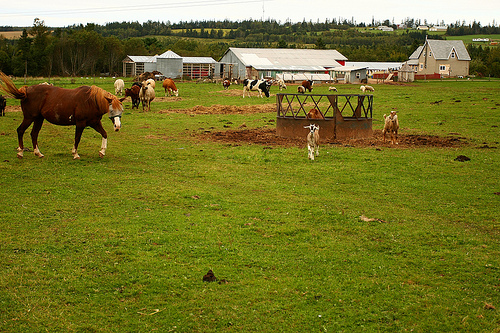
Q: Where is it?
A: This is at the field.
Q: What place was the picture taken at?
A: It was taken at the field.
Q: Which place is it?
A: It is a field.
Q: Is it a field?
A: Yes, it is a field.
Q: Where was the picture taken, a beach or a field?
A: It was taken at a field.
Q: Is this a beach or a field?
A: It is a field.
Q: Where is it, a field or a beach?
A: It is a field.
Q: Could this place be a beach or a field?
A: It is a field.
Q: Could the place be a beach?
A: No, it is a field.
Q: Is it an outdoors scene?
A: Yes, it is outdoors.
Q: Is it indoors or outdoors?
A: It is outdoors.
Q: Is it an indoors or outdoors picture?
A: It is outdoors.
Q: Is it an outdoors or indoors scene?
A: It is outdoors.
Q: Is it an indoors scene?
A: No, it is outdoors.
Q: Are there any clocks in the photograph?
A: No, there are no clocks.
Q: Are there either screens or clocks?
A: No, there are no clocks or screens.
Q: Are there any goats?
A: Yes, there is a goat.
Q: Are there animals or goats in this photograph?
A: Yes, there is a goat.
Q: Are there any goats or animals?
A: Yes, there is a goat.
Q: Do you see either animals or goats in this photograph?
A: Yes, there is a goat.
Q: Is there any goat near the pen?
A: Yes, there is a goat near the pen.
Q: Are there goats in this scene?
A: Yes, there is a goat.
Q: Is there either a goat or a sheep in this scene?
A: Yes, there is a goat.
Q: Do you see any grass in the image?
A: Yes, there is grass.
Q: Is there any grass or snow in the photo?
A: Yes, there is grass.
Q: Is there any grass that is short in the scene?
A: Yes, there is short grass.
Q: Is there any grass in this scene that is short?
A: Yes, there is grass that is short.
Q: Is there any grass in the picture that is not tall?
A: Yes, there is short grass.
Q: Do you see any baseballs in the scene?
A: No, there are no baseballs.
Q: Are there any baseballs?
A: No, there are no baseballs.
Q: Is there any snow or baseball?
A: No, there are no baseballs or snow.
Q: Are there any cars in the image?
A: No, there are no cars.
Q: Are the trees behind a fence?
A: No, the trees are behind a barn.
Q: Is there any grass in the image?
A: Yes, there is grass.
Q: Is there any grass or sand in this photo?
A: Yes, there is grass.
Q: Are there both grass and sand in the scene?
A: No, there is grass but no sand.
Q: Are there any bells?
A: No, there are no bells.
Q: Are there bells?
A: No, there are no bells.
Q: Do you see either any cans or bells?
A: No, there are no bells or cans.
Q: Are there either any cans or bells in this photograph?
A: No, there are no bells or cans.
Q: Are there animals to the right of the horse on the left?
A: Yes, there is an animal to the right of the horse.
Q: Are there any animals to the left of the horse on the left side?
A: No, the animal is to the right of the horse.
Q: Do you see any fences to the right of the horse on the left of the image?
A: No, there is an animal to the right of the horse.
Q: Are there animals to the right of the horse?
A: Yes, there is an animal to the right of the horse.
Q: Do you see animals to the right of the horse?
A: Yes, there is an animal to the right of the horse.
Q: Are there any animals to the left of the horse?
A: No, the animal is to the right of the horse.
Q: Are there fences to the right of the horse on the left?
A: No, there is an animal to the right of the horse.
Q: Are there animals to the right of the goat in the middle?
A: Yes, there is an animal to the right of the goat.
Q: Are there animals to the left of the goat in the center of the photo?
A: No, the animal is to the right of the goat.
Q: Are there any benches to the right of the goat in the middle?
A: No, there is an animal to the right of the goat.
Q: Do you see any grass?
A: Yes, there is grass.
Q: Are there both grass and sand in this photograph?
A: No, there is grass but no sand.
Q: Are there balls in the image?
A: No, there are no balls.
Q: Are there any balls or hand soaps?
A: No, there are no balls or hand soaps.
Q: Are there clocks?
A: No, there are no clocks.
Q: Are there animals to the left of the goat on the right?
A: Yes, there is an animal to the left of the goat.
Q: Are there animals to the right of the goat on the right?
A: No, the animal is to the left of the goat.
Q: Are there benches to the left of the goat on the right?
A: No, there is an animal to the left of the goat.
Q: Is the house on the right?
A: Yes, the house is on the right of the image.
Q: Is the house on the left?
A: No, the house is on the right of the image.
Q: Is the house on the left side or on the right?
A: The house is on the right of the image.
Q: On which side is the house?
A: The house is on the right of the image.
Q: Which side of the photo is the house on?
A: The house is on the right of the image.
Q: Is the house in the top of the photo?
A: Yes, the house is in the top of the image.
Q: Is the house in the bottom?
A: No, the house is in the top of the image.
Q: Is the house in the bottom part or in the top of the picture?
A: The house is in the top of the image.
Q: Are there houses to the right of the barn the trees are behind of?
A: Yes, there is a house to the right of the barn.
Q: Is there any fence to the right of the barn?
A: No, there is a house to the right of the barn.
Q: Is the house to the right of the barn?
A: Yes, the house is to the right of the barn.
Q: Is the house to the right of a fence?
A: No, the house is to the right of the barn.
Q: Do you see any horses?
A: Yes, there is a horse.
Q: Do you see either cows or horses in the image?
A: Yes, there is a horse.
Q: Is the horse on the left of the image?
A: Yes, the horse is on the left of the image.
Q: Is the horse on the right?
A: No, the horse is on the left of the image.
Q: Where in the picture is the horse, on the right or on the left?
A: The horse is on the left of the image.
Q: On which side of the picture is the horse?
A: The horse is on the left of the image.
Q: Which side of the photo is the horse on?
A: The horse is on the left of the image.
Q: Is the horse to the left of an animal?
A: Yes, the horse is to the left of an animal.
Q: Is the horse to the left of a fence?
A: No, the horse is to the left of an animal.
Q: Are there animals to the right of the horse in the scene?
A: Yes, there is an animal to the right of the horse.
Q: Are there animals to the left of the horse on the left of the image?
A: No, the animal is to the right of the horse.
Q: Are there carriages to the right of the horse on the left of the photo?
A: No, there is an animal to the right of the horse.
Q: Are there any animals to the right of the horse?
A: Yes, there is an animal to the right of the horse.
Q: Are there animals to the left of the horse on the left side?
A: No, the animal is to the right of the horse.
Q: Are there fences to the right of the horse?
A: No, there is an animal to the right of the horse.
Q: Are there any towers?
A: No, there are no towers.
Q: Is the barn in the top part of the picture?
A: Yes, the barn is in the top of the image.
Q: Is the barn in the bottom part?
A: No, the barn is in the top of the image.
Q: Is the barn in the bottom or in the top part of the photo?
A: The barn is in the top of the image.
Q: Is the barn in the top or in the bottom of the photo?
A: The barn is in the top of the image.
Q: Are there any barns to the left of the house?
A: Yes, there is a barn to the left of the house.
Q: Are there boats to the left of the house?
A: No, there is a barn to the left of the house.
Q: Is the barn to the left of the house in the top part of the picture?
A: Yes, the barn is to the left of the house.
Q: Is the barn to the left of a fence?
A: No, the barn is to the left of the house.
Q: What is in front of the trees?
A: The barn is in front of the trees.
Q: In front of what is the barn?
A: The barn is in front of the trees.